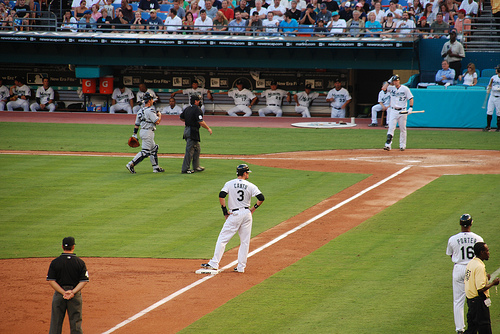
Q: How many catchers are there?
A: One.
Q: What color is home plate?
A: White.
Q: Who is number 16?
A: Porter.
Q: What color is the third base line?
A: White.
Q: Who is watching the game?
A: Fans.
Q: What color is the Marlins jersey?
A: White.